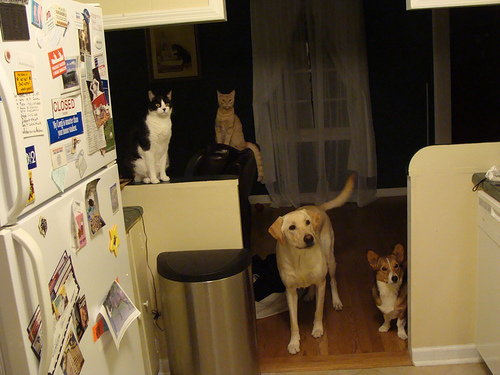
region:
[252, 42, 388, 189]
curtains on a window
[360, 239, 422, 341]
little brown and white dog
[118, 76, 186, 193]
a black and white cat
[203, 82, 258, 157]
a yellow cat sitting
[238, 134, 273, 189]
tail of a cat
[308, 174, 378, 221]
tail of a dog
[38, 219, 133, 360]
post on a refrigerator door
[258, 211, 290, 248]
ear of a dog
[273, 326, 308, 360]
paw of a dog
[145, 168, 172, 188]
paws of a cat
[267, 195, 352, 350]
brown dog staring intently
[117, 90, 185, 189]
black and white cat sitting on the counter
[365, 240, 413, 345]
small brown,black and white dog looking around cornrer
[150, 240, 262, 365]
silver trash can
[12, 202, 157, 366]
fridge door with a lot of objects tacked to it's surface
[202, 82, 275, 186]
brown cat in shadows sitting on table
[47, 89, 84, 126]
white sign with red letters that say closed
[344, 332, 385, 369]
brown wood flooring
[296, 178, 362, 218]
brown tail of a dog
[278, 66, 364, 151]
white sheer curtain hanging over window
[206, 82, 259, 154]
cat on a table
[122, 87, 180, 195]
cat on a shelf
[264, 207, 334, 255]
head of a dog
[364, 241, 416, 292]
head of a dog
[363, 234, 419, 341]
a little dog looking at something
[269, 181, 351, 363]
a big dog looking at something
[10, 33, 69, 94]
magnets on a refrigerator doot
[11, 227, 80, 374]
a handle on a refrigerator door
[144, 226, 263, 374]
stainless steel trash can with a black lid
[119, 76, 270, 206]
Two cats sitting on kitchen counter.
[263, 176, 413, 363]
Two dogs looking in kitchen.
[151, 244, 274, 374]
Stainless steel trash can in kitchen.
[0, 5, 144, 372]
Refrigerator covered with paper and magnets.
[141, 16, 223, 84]
Picture hanging on wall.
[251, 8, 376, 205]
Sheer curtains hanging at window.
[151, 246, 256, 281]
Black top on stainless steel trash can.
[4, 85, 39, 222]
Handle on freezer part of refrigerator.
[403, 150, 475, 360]
Beige half wall leading into kitchen.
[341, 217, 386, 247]
A brown laminate floor.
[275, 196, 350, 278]
the dog is brown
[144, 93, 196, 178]
the cat is black and white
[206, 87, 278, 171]
the cat is brown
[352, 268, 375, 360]
the floor is wooden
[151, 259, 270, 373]
the trash can has black lid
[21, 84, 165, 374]
the fridge is white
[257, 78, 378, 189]
the curtain is white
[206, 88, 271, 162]
the cat is standing on the chair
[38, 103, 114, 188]
there are photos on the fridge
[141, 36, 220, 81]
the photo is on the wall